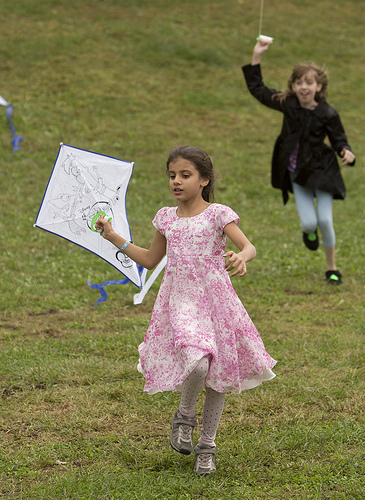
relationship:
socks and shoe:
[178, 356, 226, 446] [168, 410, 196, 455]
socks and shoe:
[178, 356, 226, 446] [193, 440, 216, 475]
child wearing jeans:
[241, 34, 357, 284] [292, 178, 337, 245]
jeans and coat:
[292, 178, 337, 245] [242, 61, 354, 197]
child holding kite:
[95, 145, 278, 477] [32, 140, 167, 306]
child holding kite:
[241, 34, 357, 284] [32, 140, 167, 306]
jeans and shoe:
[292, 180, 337, 247] [301, 229, 320, 250]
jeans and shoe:
[292, 180, 337, 247] [324, 268, 342, 285]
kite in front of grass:
[255, 0, 269, 37] [0, 0, 363, 497]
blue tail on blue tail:
[86, 265, 144, 305] [86, 274, 128, 304]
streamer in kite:
[141, 252, 168, 308] [41, 133, 158, 299]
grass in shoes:
[251, 221, 363, 336] [300, 227, 341, 283]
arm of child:
[242, 58, 277, 109] [241, 38, 355, 285]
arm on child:
[93, 213, 167, 271] [95, 145, 278, 477]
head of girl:
[152, 140, 221, 240] [127, 121, 257, 359]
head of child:
[290, 63, 322, 104] [241, 38, 355, 285]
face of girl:
[168, 162, 194, 203] [109, 138, 273, 461]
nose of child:
[171, 174, 180, 184] [95, 145, 278, 477]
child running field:
[95, 145, 278, 477] [14, 374, 305, 474]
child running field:
[241, 34, 357, 284] [14, 374, 305, 474]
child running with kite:
[241, 34, 357, 284] [249, 0, 286, 36]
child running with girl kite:
[95, 145, 278, 477] [32, 141, 168, 307]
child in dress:
[95, 145, 278, 477] [147, 207, 284, 395]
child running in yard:
[241, 34, 357, 284] [267, 260, 349, 437]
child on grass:
[241, 34, 357, 284] [50, 356, 96, 438]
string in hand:
[255, 4, 271, 51] [232, 26, 281, 56]